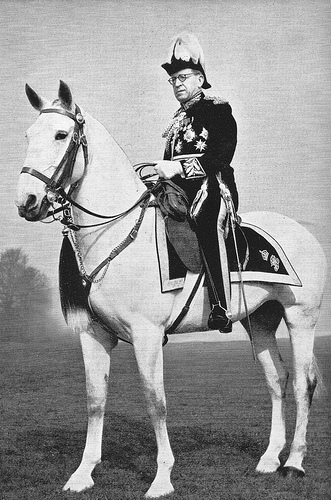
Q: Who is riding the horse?
A: A man.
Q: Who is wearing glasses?
A: A man.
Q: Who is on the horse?
A: A military man.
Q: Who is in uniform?
A: The man on the horse.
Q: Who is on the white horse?
A: A man in uniform.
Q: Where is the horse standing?
A: On a grassy area.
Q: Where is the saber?
A: On the man's side.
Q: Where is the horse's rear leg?
A: Near the tail.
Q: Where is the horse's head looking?
A: To the left.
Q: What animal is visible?
A: Horse.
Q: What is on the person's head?
A: Hat.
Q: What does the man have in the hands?
A: Reins.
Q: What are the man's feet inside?
A: Stirrups.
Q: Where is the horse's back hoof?
A: Back left side.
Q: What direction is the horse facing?
A: Left.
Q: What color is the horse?
A: White.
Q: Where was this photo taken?
A: In a field.